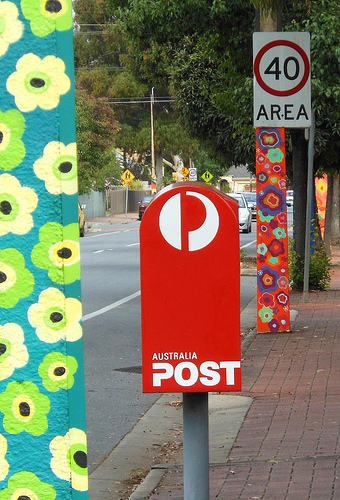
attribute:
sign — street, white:
[248, 25, 316, 131]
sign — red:
[135, 181, 247, 400]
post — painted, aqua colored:
[1, 0, 93, 499]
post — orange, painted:
[250, 122, 293, 340]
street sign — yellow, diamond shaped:
[116, 167, 137, 190]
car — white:
[222, 189, 255, 237]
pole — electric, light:
[144, 83, 158, 185]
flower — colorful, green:
[29, 220, 84, 288]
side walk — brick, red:
[148, 259, 339, 500]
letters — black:
[253, 102, 309, 125]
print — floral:
[2, 50, 76, 121]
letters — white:
[146, 346, 241, 391]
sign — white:
[186, 164, 198, 183]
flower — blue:
[255, 265, 280, 295]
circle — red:
[253, 39, 311, 99]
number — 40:
[262, 53, 301, 82]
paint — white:
[80, 285, 145, 325]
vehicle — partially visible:
[76, 197, 91, 244]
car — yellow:
[78, 201, 88, 235]